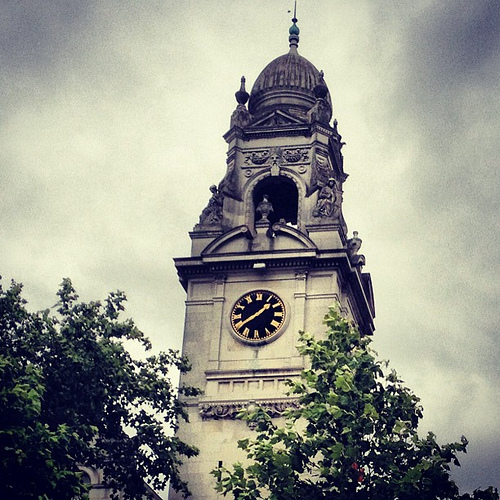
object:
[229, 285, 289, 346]
clock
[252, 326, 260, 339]
numbers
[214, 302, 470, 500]
tree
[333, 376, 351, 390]
leaf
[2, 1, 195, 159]
sky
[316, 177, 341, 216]
statue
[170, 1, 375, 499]
clock tower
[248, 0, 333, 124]
cathedral roof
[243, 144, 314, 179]
engraving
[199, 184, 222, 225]
statue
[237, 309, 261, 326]
hands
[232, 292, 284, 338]
1:39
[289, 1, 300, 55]
spire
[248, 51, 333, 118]
dome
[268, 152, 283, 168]
face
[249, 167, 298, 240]
arch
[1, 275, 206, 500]
tree